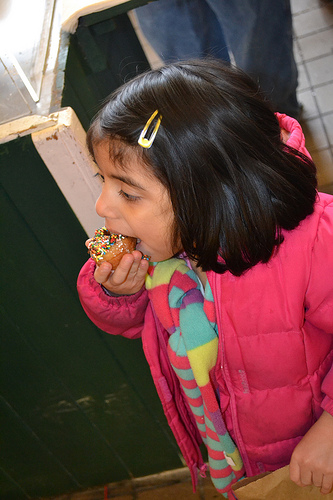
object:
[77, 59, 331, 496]
girl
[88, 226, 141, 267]
donut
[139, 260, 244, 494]
scarf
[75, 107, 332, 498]
coat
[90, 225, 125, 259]
sprinkles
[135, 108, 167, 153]
barette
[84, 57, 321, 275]
hair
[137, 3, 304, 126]
person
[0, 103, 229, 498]
wall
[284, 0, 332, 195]
floor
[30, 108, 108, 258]
trim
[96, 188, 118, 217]
nose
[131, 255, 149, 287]
fingers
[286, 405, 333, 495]
hand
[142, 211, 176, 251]
cheeks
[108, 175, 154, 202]
eyebrows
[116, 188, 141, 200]
eyes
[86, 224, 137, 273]
pastry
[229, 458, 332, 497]
bag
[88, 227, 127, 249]
candy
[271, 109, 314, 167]
hood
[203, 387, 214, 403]
colors